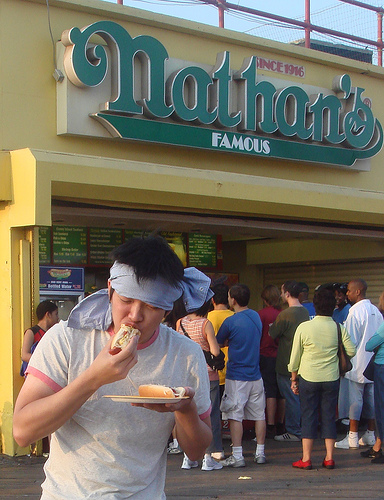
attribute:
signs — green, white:
[35, 220, 49, 264]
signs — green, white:
[50, 222, 89, 269]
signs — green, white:
[87, 223, 125, 267]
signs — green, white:
[124, 225, 153, 243]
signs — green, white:
[184, 231, 219, 268]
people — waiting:
[196, 285, 377, 456]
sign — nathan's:
[64, 19, 381, 169]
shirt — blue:
[215, 311, 260, 377]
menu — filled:
[19, 220, 241, 283]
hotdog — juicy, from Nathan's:
[137, 383, 181, 398]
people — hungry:
[7, 232, 379, 495]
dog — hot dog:
[92, 315, 150, 357]